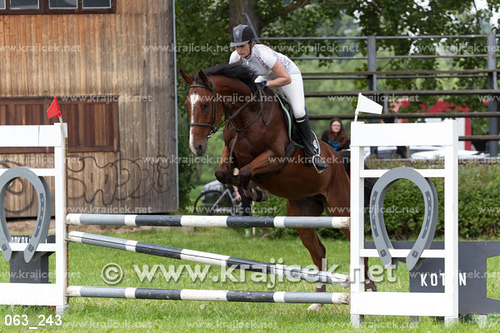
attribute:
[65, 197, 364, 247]
pole — long, black, white, gray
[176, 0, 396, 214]
tree — green, large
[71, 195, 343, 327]
barrier — black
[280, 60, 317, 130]
pants — white 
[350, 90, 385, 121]
flag — white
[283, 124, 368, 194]
boot — long, black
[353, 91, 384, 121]
flag — white, small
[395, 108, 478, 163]
trailer — Red 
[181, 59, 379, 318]
horse — brown 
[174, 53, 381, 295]
horse — large, brown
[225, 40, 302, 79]
shirt — white 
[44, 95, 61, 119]
flag — small, red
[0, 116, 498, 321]
barrier — white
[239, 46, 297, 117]
woman — long haired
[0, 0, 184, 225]
building — brown, wood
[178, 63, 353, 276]
horse — jumping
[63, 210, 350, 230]
pole — gray , black , white 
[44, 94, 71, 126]
flag — Small , red 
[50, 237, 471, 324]
grass — green